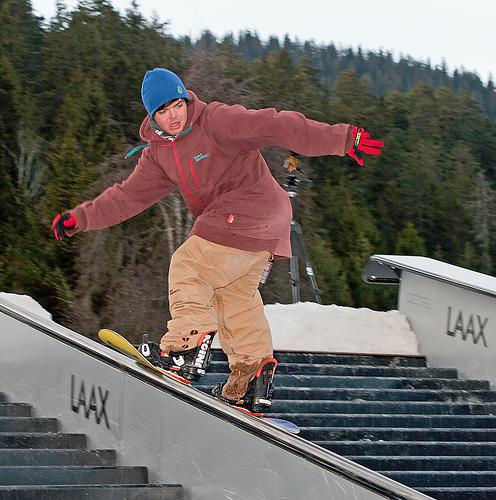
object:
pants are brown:
[158, 235, 273, 399]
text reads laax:
[447, 305, 489, 347]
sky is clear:
[0, 0, 495, 88]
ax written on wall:
[70, 374, 110, 428]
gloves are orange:
[347, 125, 383, 166]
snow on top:
[210, 300, 419, 358]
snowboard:
[98, 329, 301, 435]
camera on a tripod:
[279, 154, 311, 198]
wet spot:
[223, 361, 259, 397]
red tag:
[227, 214, 235, 223]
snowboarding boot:
[213, 358, 277, 413]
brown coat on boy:
[72, 89, 350, 258]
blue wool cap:
[141, 68, 189, 116]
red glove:
[51, 211, 76, 241]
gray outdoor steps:
[0, 485, 186, 500]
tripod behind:
[258, 219, 323, 304]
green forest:
[2, 0, 495, 303]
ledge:
[0, 305, 433, 499]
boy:
[53, 67, 383, 402]